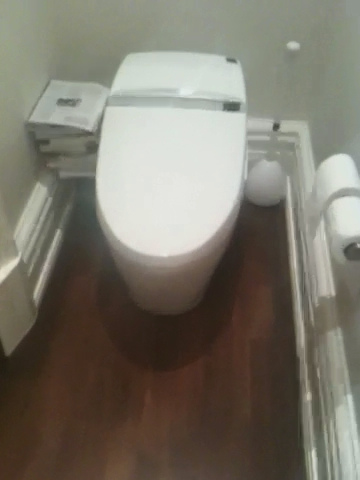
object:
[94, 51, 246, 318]
toliet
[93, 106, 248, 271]
lid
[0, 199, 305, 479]
floor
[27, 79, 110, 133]
newspaper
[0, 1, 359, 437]
wall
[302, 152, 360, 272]
toliet paper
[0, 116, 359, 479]
border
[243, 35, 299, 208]
toilet bowl cleaner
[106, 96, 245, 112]
stripe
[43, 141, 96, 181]
books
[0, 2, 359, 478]
bathroom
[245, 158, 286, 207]
base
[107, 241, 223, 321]
bottom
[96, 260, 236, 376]
shadow